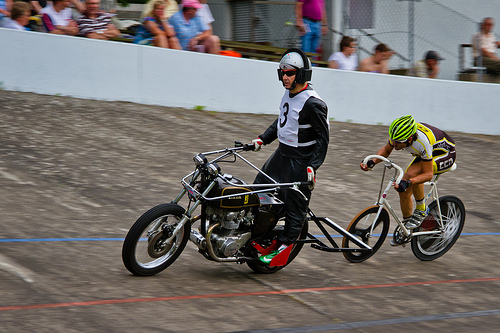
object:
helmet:
[279, 50, 315, 67]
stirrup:
[279, 257, 284, 263]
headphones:
[305, 71, 313, 78]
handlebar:
[299, 180, 314, 186]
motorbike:
[124, 140, 370, 280]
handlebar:
[225, 150, 237, 151]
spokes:
[438, 224, 457, 243]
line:
[0, 232, 500, 241]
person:
[340, 38, 357, 57]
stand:
[143, 50, 209, 89]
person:
[182, 2, 215, 22]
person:
[88, 0, 102, 12]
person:
[16, 3, 35, 22]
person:
[305, 7, 324, 20]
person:
[481, 20, 489, 43]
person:
[377, 45, 390, 59]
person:
[411, 45, 443, 70]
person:
[158, 2, 170, 21]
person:
[55, 4, 67, 19]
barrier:
[0, 25, 499, 132]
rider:
[279, 54, 322, 170]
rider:
[389, 117, 454, 196]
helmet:
[386, 116, 420, 140]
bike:
[342, 153, 472, 266]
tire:
[357, 209, 388, 251]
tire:
[440, 204, 461, 245]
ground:
[3, 89, 500, 332]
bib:
[278, 99, 295, 129]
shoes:
[391, 206, 427, 235]